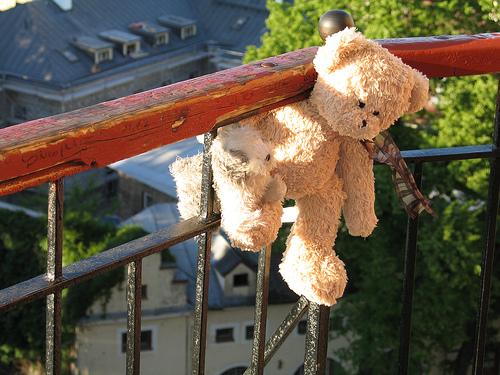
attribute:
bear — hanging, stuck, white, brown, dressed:
[184, 40, 438, 310]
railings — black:
[6, 78, 492, 372]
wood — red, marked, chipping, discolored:
[3, 29, 492, 180]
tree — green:
[249, 4, 493, 362]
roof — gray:
[2, 1, 291, 82]